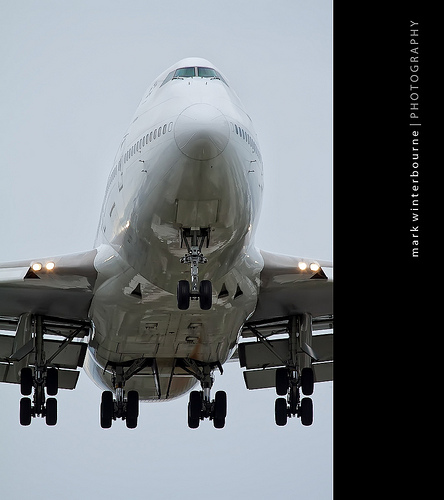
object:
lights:
[45, 262, 54, 270]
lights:
[298, 261, 307, 270]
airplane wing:
[238, 251, 339, 427]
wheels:
[199, 280, 214, 310]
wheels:
[299, 397, 315, 426]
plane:
[0, 65, 332, 433]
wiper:
[172, 76, 185, 81]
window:
[159, 66, 196, 88]